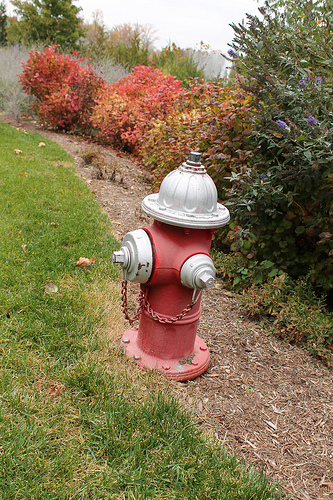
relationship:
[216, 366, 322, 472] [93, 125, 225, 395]
wood chips near hydrant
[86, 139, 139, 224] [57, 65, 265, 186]
mulch near bushes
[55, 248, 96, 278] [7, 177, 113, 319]
leaf on grass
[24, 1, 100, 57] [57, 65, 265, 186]
tree behind bushes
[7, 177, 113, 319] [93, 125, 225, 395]
grass near hydrant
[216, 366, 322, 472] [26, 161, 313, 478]
wood chips on ground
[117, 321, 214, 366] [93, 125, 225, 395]
bolts on hydrant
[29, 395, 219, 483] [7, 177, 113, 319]
hay on grass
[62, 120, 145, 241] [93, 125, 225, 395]
path behind hydrant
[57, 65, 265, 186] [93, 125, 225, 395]
bushes behind hydrant